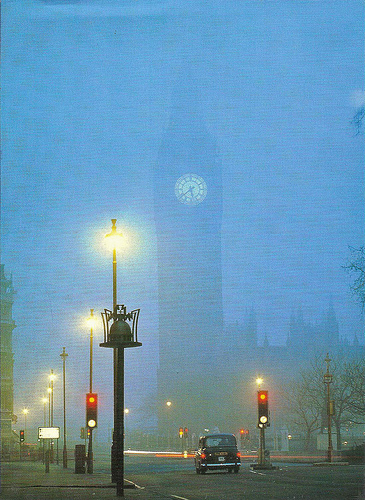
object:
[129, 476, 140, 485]
edge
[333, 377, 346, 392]
part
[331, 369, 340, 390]
branch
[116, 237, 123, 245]
part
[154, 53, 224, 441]
building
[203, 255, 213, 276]
part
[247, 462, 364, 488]
side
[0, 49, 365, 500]
city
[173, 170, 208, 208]
clock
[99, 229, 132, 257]
light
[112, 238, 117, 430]
pole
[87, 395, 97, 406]
light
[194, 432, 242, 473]
car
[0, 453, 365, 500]
road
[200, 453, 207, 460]
light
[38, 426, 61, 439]
sign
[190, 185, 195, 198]
hands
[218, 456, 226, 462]
license plate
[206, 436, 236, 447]
window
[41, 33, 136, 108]
fog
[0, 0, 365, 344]
sky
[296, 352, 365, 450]
tree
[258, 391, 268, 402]
light